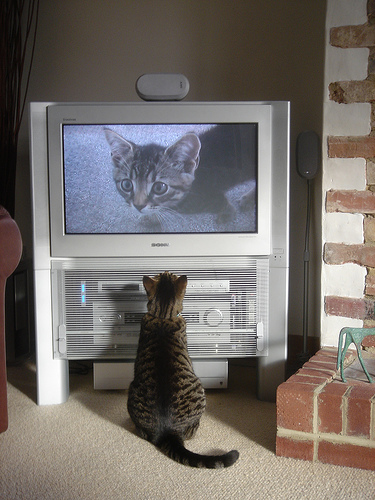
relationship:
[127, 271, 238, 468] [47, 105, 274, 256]
cat in front of tv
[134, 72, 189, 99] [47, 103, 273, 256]
speaker on t.v.